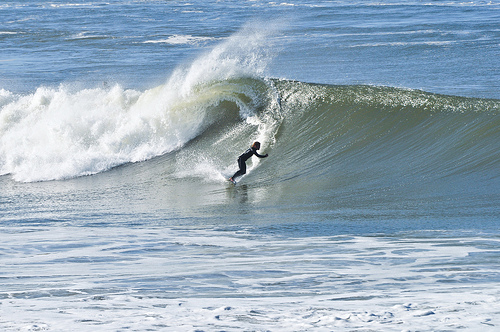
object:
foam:
[1, 8, 296, 184]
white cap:
[2, 76, 278, 185]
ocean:
[2, 2, 499, 329]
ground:
[0, 0, 500, 332]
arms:
[255, 151, 266, 158]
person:
[229, 142, 268, 184]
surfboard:
[227, 177, 236, 185]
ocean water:
[0, 0, 499, 331]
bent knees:
[238, 164, 246, 175]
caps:
[251, 142, 259, 150]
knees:
[240, 170, 246, 175]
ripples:
[0, 231, 500, 329]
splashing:
[0, 12, 294, 183]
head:
[251, 142, 260, 150]